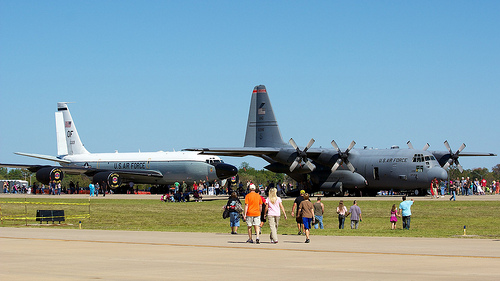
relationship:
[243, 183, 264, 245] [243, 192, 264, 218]
person wearing t-shirt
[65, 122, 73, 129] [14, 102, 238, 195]
flag on airplane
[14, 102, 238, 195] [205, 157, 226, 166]
airplane has cockpit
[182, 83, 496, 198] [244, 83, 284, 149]
airplane has tail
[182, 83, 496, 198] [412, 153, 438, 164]
airplane has cockpit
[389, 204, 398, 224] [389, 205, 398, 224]
girl wearing dress